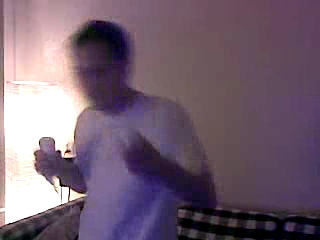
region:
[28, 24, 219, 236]
the man is blurry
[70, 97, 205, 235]
the t shirt is blurry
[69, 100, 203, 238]
the man is wearing a short sleeve shirt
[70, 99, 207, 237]
the shirt is white in color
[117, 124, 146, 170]
the man is holding a remote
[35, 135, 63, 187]
the man is holding a remote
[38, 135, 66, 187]
the remote is a game controller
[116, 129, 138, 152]
the remote is blurry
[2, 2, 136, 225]
a window is besides the man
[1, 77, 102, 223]
the window is bright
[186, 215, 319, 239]
a black and white sofa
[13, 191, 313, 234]
a sofa in the background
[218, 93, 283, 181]
a white wall behind the sofa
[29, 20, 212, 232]
a blurry man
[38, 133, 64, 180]
a remote the man is holding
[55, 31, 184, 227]
a man wearing a white shirt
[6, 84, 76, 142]
a lamp in the background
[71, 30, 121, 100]
the face of the man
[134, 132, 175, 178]
the arm of the man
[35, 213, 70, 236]
a pillow on the sofa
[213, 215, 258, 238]
a couch pillow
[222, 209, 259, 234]
the couch is black and white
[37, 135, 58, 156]
object in hand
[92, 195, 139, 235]
a white shirt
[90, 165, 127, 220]
the shirt is white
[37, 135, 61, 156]
the man is holding an object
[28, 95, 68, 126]
light on the wall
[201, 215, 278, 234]
a couch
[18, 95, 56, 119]
the wall has light on it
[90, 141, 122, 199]
the shirt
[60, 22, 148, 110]
head of a person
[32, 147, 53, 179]
fingers of a person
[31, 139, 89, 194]
arm of a person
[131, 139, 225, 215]
arm of a person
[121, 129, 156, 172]
hand of a person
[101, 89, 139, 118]
neck of a person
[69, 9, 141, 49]
hair of a person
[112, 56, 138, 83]
ear of a person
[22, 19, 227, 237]
person wearing a white shirt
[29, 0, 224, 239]
man wearing white shirt